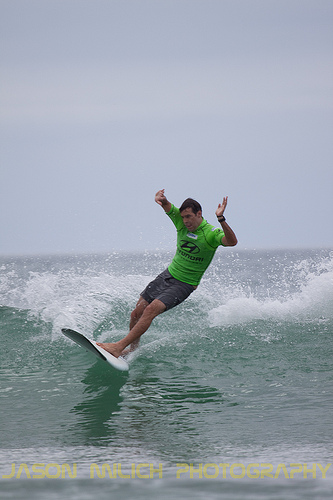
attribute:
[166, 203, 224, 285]
shirt — green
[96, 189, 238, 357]
man — here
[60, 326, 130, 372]
board — white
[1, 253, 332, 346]
wave — white, large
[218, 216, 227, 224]
watch — black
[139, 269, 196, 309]
shorts — tan, black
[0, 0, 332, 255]
sky — cloudy, blue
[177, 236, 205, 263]
logo — black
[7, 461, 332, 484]
letters — yellow, written